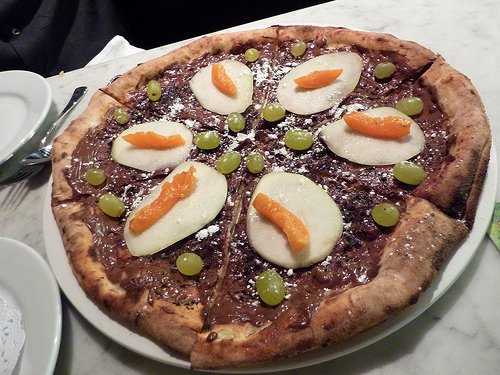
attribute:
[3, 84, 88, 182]
fork — silver, pictured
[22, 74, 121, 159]
spoon — silver, shiny, pictured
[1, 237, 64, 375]
plate — white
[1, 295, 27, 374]
doily — white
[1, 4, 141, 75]
shirt — black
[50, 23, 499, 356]
pizza — large, white, brown, green orange, sliced, chocolate, fruit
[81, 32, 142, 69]
napkin — white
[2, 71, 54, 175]
plate — pictured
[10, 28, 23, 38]
button — black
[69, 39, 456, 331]
sauce — chocolate, brown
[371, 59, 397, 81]
grape — green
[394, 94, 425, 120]
grape — green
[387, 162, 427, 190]
grape — green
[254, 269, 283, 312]
grape — green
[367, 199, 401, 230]
grape — green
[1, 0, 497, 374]
table — white marble, streaked, white, marble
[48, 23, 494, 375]
crust — baked, brown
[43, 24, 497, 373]
plate — white, round